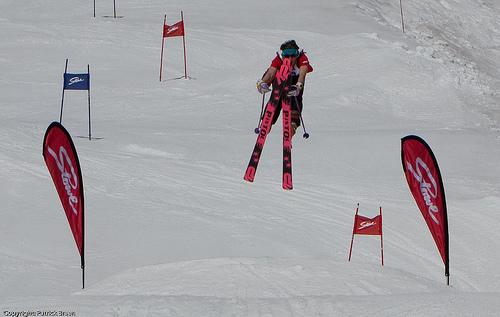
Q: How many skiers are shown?
A: 1.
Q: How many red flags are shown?
A: 4.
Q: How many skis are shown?
A: 2.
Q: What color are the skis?
A: Pink.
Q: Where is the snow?
A: On the ground.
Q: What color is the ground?
A: White.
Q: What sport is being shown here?
A: Skiing.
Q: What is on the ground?
A: Snow.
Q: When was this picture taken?
A: Winter.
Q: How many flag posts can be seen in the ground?
A: Six.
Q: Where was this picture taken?
A: Ski slope.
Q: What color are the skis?
A: Pink.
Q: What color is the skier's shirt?
A: Red.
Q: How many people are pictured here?
A: One.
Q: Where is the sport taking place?
A: Ski slope.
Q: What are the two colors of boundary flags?
A: Red and blue.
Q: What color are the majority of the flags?
A: Red.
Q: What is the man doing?
A: Skiing.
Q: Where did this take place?
A: In the snow.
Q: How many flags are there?
A: Six.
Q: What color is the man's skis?
A: Pink.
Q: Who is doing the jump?
A: The skier.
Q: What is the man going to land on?
A: The snow.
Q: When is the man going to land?
A: When he finishes the jump.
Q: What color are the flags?
A: Red and blue.